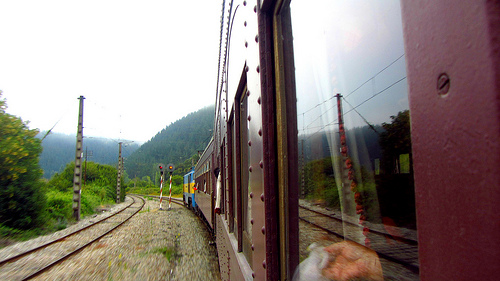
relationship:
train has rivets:
[178, 0, 499, 280] [250, 34, 271, 126]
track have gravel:
[2, 193, 147, 279] [60, 205, 180, 279]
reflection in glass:
[317, 57, 394, 182] [276, 3, 409, 279]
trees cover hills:
[152, 128, 190, 147] [124, 103, 214, 195]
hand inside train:
[322, 233, 383, 280] [178, 0, 499, 280]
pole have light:
[168, 173, 172, 213] [156, 163, 163, 170]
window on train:
[276, 3, 409, 279] [178, 0, 499, 280]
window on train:
[229, 90, 260, 277] [178, 0, 499, 280]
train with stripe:
[178, 0, 499, 280] [177, 182, 200, 194]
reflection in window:
[317, 57, 394, 182] [276, 3, 409, 279]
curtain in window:
[303, 46, 391, 251] [276, 3, 409, 279]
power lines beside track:
[84, 102, 148, 171] [2, 197, 129, 267]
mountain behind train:
[124, 103, 214, 195] [178, 0, 499, 280]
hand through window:
[322, 233, 383, 280] [276, 3, 409, 279]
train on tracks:
[178, 0, 499, 280] [156, 193, 186, 207]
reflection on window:
[317, 57, 394, 182] [276, 3, 409, 279]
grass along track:
[3, 188, 101, 252] [2, 193, 147, 279]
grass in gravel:
[157, 243, 181, 266] [60, 205, 180, 279]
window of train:
[229, 90, 260, 277] [178, 0, 499, 280]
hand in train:
[322, 233, 383, 280] [178, 0, 499, 280]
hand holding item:
[322, 233, 383, 280] [297, 242, 330, 281]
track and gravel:
[2, 193, 147, 279] [60, 205, 180, 279]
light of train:
[156, 163, 163, 170] [178, 0, 499, 280]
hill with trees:
[124, 103, 214, 195] [152, 128, 190, 147]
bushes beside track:
[3, 120, 53, 226] [2, 193, 147, 279]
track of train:
[2, 193, 147, 279] [178, 0, 499, 280]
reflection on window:
[317, 57, 394, 182] [229, 90, 260, 277]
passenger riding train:
[316, 230, 425, 280] [178, 0, 499, 280]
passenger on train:
[316, 230, 425, 280] [178, 0, 499, 280]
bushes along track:
[3, 120, 53, 226] [2, 193, 147, 279]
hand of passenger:
[322, 233, 383, 280] [316, 230, 425, 280]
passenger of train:
[316, 230, 425, 280] [178, 0, 499, 280]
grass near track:
[3, 188, 101, 252] [2, 193, 147, 279]